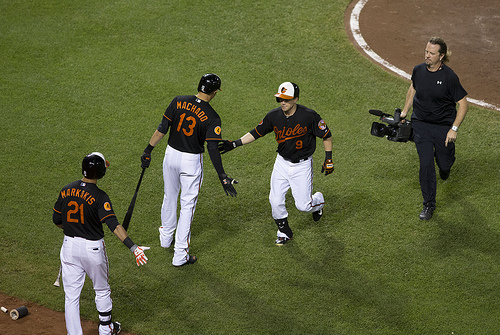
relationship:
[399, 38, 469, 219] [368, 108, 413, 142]
camera man carrying a camera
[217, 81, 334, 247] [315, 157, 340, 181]
player wearing gloves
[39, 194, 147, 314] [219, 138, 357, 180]
player wearing gloves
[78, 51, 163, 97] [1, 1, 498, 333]
turf on baseball field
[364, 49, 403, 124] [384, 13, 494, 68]
dirt mound on pitchers mound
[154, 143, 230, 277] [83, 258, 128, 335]
pants uniforms are white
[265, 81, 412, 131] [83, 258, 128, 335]
wall uniforms are white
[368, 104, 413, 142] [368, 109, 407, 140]
camera in hand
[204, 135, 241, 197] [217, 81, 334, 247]
gloves on player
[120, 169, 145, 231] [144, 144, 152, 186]
baseball bat in mans hand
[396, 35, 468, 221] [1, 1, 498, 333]
camera man shadow on field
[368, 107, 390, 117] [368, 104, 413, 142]
microphone on camera